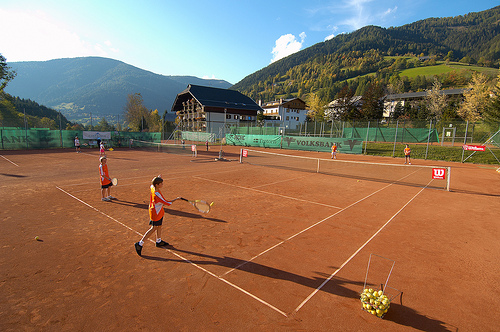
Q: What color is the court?
A: Orange.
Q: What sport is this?
A: Tennis.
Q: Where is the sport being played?
A: Tennis court.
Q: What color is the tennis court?
A: Brown.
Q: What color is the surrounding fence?
A: Silver.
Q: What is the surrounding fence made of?
A: Metal.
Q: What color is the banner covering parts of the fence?
A: Green.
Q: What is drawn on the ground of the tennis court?
A: White lines.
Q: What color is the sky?
A: Blue and white.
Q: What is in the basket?
A: Balls.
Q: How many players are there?
A: 4.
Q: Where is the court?
A: In the dirt.